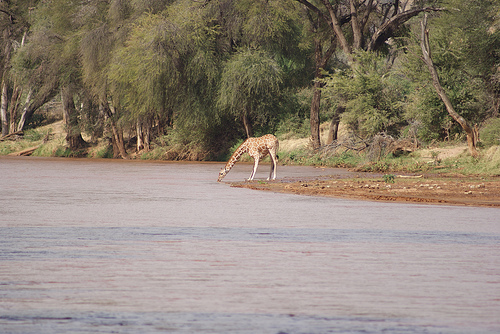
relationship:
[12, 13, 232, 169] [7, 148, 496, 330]
trees on shore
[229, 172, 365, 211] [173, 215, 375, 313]
dirt by water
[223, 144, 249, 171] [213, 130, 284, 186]
neck on giraffe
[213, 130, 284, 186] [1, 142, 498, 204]
giraffe drinking at lake edge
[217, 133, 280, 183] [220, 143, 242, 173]
giraffe has neck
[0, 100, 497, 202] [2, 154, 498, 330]
dirt near lake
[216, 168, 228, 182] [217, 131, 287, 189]
head of giraffe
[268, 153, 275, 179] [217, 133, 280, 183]
back legs of giraffe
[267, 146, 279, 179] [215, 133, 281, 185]
back legs of giraffe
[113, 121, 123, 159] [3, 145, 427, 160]
trunk near edge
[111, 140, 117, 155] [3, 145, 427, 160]
trunk near edge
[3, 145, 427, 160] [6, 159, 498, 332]
edge of water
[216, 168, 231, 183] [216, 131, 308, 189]
mouth of giraffe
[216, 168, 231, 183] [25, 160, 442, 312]
mouth in water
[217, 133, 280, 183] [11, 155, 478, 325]
giraffe drinking water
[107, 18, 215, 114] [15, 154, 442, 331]
green tree near water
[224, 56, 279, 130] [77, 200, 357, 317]
tree near water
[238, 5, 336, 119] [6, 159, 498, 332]
tree near water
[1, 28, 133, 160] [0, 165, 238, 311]
tree near water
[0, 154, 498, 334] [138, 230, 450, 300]
lake has water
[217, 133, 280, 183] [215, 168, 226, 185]
giraffe has head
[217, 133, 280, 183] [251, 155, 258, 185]
giraffe has leg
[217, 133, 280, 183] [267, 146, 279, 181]
giraffe has back legs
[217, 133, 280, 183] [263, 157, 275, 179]
giraffe has back legs